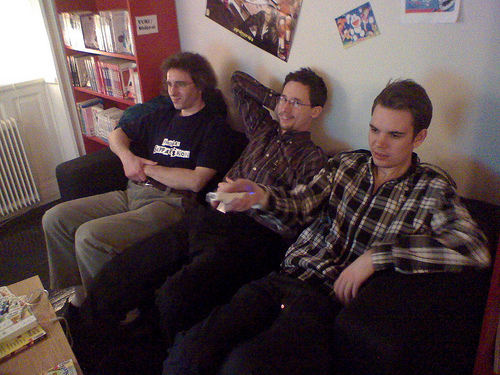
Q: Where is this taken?
A: A private residence.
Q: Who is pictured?
A: Three men.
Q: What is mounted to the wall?
A: A radiator.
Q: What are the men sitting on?
A: A couch.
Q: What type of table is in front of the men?
A: Wooden.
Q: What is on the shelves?
A: Books.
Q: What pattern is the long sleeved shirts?
A: Plaid.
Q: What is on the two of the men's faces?
A: Eyeglasses.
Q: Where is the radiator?
A: On the wall.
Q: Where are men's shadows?
A: On the wall.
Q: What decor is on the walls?
A: Poster.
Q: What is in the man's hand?
A: A remote.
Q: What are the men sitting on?
A: A couch.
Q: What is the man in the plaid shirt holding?
A: A Wii controller.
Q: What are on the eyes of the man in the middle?
A: Eyeglasses.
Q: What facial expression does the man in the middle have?
A: A smile.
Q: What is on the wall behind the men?
A: Posters.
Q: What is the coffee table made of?
A: Wood.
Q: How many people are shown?
A: Three.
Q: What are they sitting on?
A: A couch.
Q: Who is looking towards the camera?
A: The person in the middle.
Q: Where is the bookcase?
A: At the left end of the couch.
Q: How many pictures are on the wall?
A: Three.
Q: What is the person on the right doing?
A: Pointing a device.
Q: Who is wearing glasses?
A: The center person.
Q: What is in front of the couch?
A: A small table.